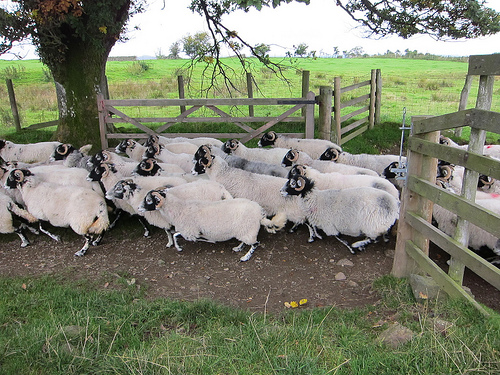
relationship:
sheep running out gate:
[280, 164, 398, 254] [313, 89, 415, 279]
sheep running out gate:
[137, 190, 262, 258] [313, 89, 415, 279]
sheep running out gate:
[6, 162, 111, 254] [313, 89, 415, 279]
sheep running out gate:
[189, 150, 294, 228] [313, 89, 415, 279]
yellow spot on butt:
[90, 215, 101, 226] [71, 187, 115, 257]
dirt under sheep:
[244, 258, 303, 286] [166, 194, 257, 250]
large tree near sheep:
[0, 0, 500, 139] [277, 175, 397, 250]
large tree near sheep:
[0, 0, 500, 139] [137, 190, 262, 258]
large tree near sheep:
[0, 0, 500, 139] [2, 168, 104, 255]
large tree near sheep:
[0, 0, 500, 139] [258, 130, 343, 162]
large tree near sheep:
[0, 0, 500, 139] [106, 181, 175, 246]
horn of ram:
[288, 178, 305, 190] [273, 164, 400, 254]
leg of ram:
[236, 238, 265, 273] [136, 181, 283, 261]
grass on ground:
[80, 280, 235, 370] [11, 243, 355, 371]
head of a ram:
[135, 189, 167, 215] [132, 189, 179, 215]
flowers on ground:
[273, 296, 310, 308] [80, 246, 235, 373]